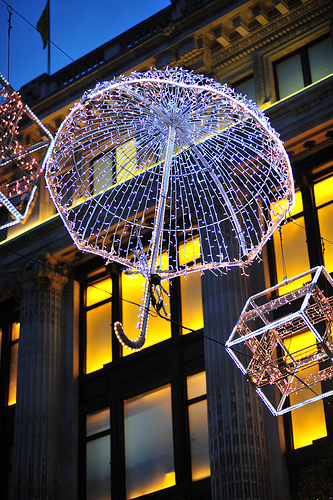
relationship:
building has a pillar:
[2, 0, 331, 499] [11, 250, 69, 500]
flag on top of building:
[37, 0, 52, 71] [2, 0, 331, 499]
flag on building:
[37, 0, 52, 71] [2, 0, 331, 499]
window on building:
[77, 272, 120, 374] [2, 0, 331, 499]